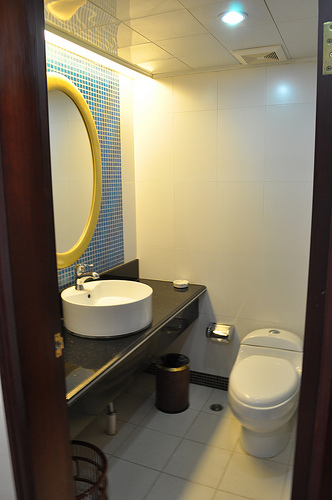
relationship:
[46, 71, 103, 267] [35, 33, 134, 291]
mirror attached to wall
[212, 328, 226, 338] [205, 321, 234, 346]
toilet paper roll on dispenser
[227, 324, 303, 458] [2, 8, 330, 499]
toilet inside room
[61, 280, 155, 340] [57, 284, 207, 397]
sink on top of counter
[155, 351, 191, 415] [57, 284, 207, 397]
trash can underneath counter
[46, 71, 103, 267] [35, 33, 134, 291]
mirror hanging on wall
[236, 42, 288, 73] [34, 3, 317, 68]
vent on surface of ceiling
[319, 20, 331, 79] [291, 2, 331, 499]
hinge on door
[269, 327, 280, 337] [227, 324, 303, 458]
button on toilet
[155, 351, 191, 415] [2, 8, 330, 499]
trash can inside of room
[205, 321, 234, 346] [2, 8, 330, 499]
dispenser inside of room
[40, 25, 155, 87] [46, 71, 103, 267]
lighting above mirror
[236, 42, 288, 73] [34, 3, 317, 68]
vent in ceiling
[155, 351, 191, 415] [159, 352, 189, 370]
trash can has lid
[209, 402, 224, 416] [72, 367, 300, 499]
drain in floor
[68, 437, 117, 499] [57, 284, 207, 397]
basket underneath counter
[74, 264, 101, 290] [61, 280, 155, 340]
faucet on top of sink